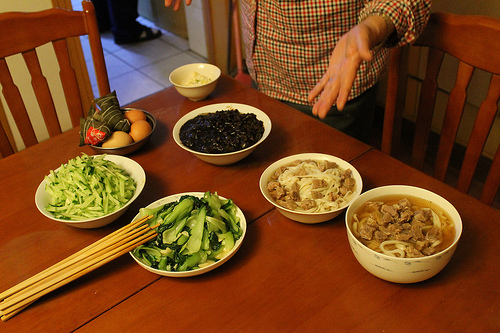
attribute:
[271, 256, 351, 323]
table — wooden, brown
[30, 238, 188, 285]
chopstick — beige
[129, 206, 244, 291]
bokchoy — green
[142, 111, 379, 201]
bowl — silver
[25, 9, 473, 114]
chairs — brown, wooden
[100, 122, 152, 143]
eggs — brown